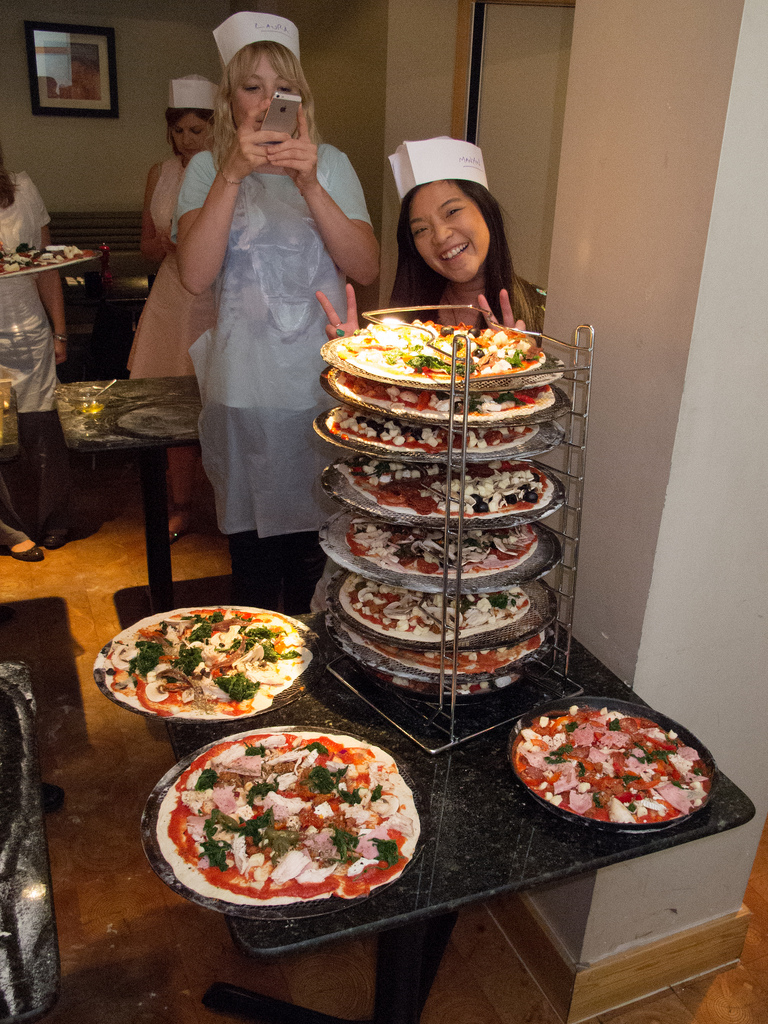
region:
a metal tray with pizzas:
[315, 308, 579, 722]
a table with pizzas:
[114, 575, 753, 942]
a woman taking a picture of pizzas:
[177, 12, 381, 575]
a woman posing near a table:
[313, 135, 552, 336]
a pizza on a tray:
[321, 320, 555, 389]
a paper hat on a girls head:
[205, 10, 303, 62]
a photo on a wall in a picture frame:
[27, 23, 123, 114]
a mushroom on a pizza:
[147, 677, 166, 700]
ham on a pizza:
[550, 770, 576, 790]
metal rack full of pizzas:
[315, 303, 573, 719]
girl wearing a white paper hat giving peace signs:
[367, 124, 498, 220]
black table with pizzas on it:
[126, 596, 658, 872]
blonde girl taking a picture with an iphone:
[213, 47, 333, 228]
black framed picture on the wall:
[30, 22, 121, 114]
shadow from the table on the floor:
[4, 591, 97, 773]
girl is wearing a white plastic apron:
[170, 110, 375, 535]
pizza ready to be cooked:
[86, 599, 312, 715]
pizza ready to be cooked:
[155, 727, 420, 909]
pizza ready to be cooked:
[510, 702, 707, 831]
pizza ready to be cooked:
[323, 319, 545, 378]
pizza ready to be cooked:
[326, 357, 556, 423]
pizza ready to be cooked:
[321, 394, 537, 451]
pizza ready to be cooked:
[334, 450, 554, 514]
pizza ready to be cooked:
[341, 511, 536, 575]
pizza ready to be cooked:
[336, 563, 523, 631]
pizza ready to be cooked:
[337, 614, 547, 672]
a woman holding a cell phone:
[244, 84, 301, 162]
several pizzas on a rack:
[323, 310, 598, 708]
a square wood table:
[52, 370, 200, 578]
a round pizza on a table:
[140, 731, 409, 925]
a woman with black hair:
[390, 166, 516, 303]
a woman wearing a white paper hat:
[385, 136, 496, 207]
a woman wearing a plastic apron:
[172, 162, 328, 480]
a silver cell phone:
[257, 92, 305, 144]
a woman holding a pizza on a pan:
[1, 234, 117, 289]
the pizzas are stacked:
[78, 73, 661, 819]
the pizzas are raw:
[125, 596, 416, 933]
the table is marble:
[399, 732, 592, 942]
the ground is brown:
[94, 899, 199, 975]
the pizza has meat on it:
[504, 699, 738, 903]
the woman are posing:
[166, 62, 503, 367]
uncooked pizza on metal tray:
[537, 655, 696, 862]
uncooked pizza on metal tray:
[307, 302, 550, 377]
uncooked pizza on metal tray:
[379, 388, 571, 445]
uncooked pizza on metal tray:
[336, 432, 530, 471]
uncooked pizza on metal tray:
[360, 461, 581, 513]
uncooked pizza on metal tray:
[336, 537, 583, 599]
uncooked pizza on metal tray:
[353, 603, 524, 632]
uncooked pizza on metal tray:
[369, 646, 584, 701]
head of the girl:
[354, 105, 551, 327]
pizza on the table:
[109, 742, 434, 932]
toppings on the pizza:
[104, 725, 418, 917]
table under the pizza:
[433, 792, 515, 866]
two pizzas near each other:
[94, 704, 713, 954]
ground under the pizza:
[78, 907, 178, 999]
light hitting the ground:
[66, 879, 153, 993]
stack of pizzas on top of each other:
[229, 272, 699, 720]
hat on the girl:
[364, 105, 536, 199]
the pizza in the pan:
[505, 692, 715, 836]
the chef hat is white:
[381, 133, 487, 205]